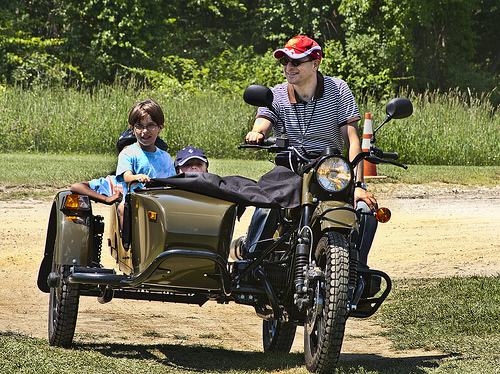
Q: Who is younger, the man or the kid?
A: The kid is younger than the man.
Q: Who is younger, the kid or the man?
A: The kid is younger than the man.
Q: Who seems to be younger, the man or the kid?
A: The kid is younger than the man.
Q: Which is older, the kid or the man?
A: The man is older than the kid.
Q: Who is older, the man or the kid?
A: The man is older than the kid.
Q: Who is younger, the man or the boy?
A: The boy is younger than the man.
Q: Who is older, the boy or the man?
A: The man is older than the boy.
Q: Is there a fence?
A: No, there are no fences.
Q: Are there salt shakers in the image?
A: No, there are no salt shakers.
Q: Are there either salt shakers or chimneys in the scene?
A: No, there are no salt shakers or chimneys.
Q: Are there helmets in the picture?
A: No, there are no helmets.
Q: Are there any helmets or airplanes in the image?
A: No, there are no helmets or airplanes.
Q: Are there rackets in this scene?
A: No, there are no rackets.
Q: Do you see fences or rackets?
A: No, there are no rackets or fences.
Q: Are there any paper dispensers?
A: No, there are no paper dispensers.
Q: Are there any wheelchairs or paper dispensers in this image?
A: No, there are no paper dispensers or wheelchairs.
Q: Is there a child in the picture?
A: Yes, there is a child.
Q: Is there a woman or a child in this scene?
A: Yes, there is a child.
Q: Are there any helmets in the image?
A: No, there are no helmets.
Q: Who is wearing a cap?
A: The child is wearing a cap.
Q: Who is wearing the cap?
A: The child is wearing a cap.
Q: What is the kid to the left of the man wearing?
A: The child is wearing a cap.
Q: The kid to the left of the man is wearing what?
A: The child is wearing a cap.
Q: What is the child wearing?
A: The child is wearing a cap.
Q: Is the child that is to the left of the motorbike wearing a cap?
A: Yes, the child is wearing a cap.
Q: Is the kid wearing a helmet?
A: No, the kid is wearing a cap.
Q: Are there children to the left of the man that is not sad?
A: Yes, there is a child to the left of the man.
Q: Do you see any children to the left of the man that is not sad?
A: Yes, there is a child to the left of the man.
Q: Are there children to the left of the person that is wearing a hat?
A: Yes, there is a child to the left of the man.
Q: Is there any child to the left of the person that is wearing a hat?
A: Yes, there is a child to the left of the man.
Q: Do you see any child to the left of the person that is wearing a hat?
A: Yes, there is a child to the left of the man.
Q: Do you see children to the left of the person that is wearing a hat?
A: Yes, there is a child to the left of the man.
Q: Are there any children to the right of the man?
A: No, the child is to the left of the man.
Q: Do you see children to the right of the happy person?
A: No, the child is to the left of the man.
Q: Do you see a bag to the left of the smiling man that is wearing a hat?
A: No, there is a child to the left of the man.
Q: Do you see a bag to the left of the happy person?
A: No, there is a child to the left of the man.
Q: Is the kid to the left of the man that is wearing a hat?
A: Yes, the kid is to the left of the man.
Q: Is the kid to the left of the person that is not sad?
A: Yes, the kid is to the left of the man.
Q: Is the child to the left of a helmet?
A: No, the child is to the left of the man.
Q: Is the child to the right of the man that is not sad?
A: No, the child is to the left of the man.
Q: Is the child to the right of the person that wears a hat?
A: No, the child is to the left of the man.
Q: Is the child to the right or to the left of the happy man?
A: The child is to the left of the man.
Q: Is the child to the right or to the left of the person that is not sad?
A: The child is to the left of the man.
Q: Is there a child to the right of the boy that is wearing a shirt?
A: Yes, there is a child to the right of the boy.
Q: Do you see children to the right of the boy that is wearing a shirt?
A: Yes, there is a child to the right of the boy.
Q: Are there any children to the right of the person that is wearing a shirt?
A: Yes, there is a child to the right of the boy.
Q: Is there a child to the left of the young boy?
A: No, the child is to the right of the boy.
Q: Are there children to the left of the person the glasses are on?
A: No, the child is to the right of the boy.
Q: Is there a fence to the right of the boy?
A: No, there is a child to the right of the boy.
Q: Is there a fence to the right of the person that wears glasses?
A: No, there is a child to the right of the boy.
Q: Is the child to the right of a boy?
A: Yes, the child is to the right of a boy.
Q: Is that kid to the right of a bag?
A: No, the kid is to the right of a boy.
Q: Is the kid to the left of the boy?
A: No, the kid is to the right of the boy.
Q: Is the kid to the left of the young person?
A: No, the kid is to the right of the boy.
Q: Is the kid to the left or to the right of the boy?
A: The kid is to the right of the boy.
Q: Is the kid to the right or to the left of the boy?
A: The kid is to the right of the boy.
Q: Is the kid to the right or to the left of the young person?
A: The kid is to the right of the boy.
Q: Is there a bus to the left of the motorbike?
A: No, there is a child to the left of the motorbike.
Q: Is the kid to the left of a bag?
A: No, the kid is to the left of the motorcycle.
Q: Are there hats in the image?
A: Yes, there is a hat.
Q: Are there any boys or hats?
A: Yes, there is a hat.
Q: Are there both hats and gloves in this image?
A: No, there is a hat but no gloves.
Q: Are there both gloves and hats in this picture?
A: No, there is a hat but no gloves.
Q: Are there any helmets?
A: No, there are no helmets.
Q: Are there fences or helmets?
A: No, there are no helmets or fences.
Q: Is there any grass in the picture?
A: Yes, there is grass.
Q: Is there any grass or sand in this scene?
A: Yes, there is grass.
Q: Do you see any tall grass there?
A: Yes, there is tall grass.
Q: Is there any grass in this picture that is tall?
A: Yes, there is grass that is tall.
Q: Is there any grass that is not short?
A: Yes, there is tall grass.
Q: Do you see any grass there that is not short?
A: Yes, there is tall grass.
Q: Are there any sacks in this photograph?
A: No, there are no sacks.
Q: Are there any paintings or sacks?
A: No, there are no sacks or paintings.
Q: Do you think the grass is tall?
A: Yes, the grass is tall.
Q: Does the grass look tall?
A: Yes, the grass is tall.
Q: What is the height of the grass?
A: The grass is tall.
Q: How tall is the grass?
A: The grass is tall.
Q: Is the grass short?
A: No, the grass is tall.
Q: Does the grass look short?
A: No, the grass is tall.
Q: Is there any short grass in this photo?
A: No, there is grass but it is tall.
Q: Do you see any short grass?
A: No, there is grass but it is tall.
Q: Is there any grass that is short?
A: No, there is grass but it is tall.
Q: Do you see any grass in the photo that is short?
A: No, there is grass but it is tall.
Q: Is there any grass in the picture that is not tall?
A: No, there is grass but it is tall.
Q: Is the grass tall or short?
A: The grass is tall.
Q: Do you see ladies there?
A: No, there are no ladies.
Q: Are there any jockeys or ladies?
A: No, there are no ladies or jockeys.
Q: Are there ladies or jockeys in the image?
A: No, there are no ladies or jockeys.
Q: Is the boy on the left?
A: Yes, the boy is on the left of the image.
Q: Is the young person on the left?
A: Yes, the boy is on the left of the image.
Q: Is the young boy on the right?
A: No, the boy is on the left of the image.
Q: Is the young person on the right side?
A: No, the boy is on the left of the image.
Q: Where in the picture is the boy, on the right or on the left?
A: The boy is on the left of the image.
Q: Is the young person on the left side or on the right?
A: The boy is on the left of the image.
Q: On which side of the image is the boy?
A: The boy is on the left of the image.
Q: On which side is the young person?
A: The boy is on the left of the image.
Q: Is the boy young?
A: Yes, the boy is young.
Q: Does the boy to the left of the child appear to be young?
A: Yes, the boy is young.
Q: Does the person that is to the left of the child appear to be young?
A: Yes, the boy is young.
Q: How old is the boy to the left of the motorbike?
A: The boy is young.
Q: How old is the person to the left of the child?
A: The boy is young.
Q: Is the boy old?
A: No, the boy is young.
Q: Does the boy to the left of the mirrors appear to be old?
A: No, the boy is young.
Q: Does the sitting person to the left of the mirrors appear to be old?
A: No, the boy is young.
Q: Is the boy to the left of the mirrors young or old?
A: The boy is young.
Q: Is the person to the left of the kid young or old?
A: The boy is young.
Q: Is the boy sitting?
A: Yes, the boy is sitting.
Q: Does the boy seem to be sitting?
A: Yes, the boy is sitting.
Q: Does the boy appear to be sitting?
A: Yes, the boy is sitting.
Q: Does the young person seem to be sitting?
A: Yes, the boy is sitting.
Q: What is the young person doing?
A: The boy is sitting.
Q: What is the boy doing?
A: The boy is sitting.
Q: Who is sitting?
A: The boy is sitting.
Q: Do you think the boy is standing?
A: No, the boy is sitting.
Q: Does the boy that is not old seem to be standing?
A: No, the boy is sitting.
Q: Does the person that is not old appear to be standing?
A: No, the boy is sitting.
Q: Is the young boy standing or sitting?
A: The boy is sitting.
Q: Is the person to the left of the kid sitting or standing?
A: The boy is sitting.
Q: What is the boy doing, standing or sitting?
A: The boy is sitting.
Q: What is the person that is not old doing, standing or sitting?
A: The boy is sitting.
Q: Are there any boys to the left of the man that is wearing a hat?
A: Yes, there is a boy to the left of the man.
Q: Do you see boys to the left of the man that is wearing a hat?
A: Yes, there is a boy to the left of the man.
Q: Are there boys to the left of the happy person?
A: Yes, there is a boy to the left of the man.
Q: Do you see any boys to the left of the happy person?
A: Yes, there is a boy to the left of the man.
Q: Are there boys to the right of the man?
A: No, the boy is to the left of the man.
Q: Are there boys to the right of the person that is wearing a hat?
A: No, the boy is to the left of the man.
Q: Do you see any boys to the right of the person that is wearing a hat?
A: No, the boy is to the left of the man.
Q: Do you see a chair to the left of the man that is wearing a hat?
A: No, there is a boy to the left of the man.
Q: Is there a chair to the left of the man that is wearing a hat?
A: No, there is a boy to the left of the man.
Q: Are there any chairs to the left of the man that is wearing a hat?
A: No, there is a boy to the left of the man.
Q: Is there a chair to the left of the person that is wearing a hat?
A: No, there is a boy to the left of the man.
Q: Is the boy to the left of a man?
A: Yes, the boy is to the left of a man.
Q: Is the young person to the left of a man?
A: Yes, the boy is to the left of a man.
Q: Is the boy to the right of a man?
A: No, the boy is to the left of a man.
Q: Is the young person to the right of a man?
A: No, the boy is to the left of a man.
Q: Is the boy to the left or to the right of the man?
A: The boy is to the left of the man.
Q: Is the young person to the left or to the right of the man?
A: The boy is to the left of the man.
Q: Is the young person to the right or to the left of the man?
A: The boy is to the left of the man.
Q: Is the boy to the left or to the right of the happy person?
A: The boy is to the left of the man.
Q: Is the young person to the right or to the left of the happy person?
A: The boy is to the left of the man.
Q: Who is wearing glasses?
A: The boy is wearing glasses.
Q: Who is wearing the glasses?
A: The boy is wearing glasses.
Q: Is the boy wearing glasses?
A: Yes, the boy is wearing glasses.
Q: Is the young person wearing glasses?
A: Yes, the boy is wearing glasses.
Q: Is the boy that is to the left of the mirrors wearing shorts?
A: No, the boy is wearing glasses.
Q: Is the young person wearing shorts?
A: No, the boy is wearing glasses.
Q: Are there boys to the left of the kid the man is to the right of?
A: Yes, there is a boy to the left of the child.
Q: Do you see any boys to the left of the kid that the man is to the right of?
A: Yes, there is a boy to the left of the child.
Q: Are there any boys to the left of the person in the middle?
A: Yes, there is a boy to the left of the child.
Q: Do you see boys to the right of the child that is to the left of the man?
A: No, the boy is to the left of the child.